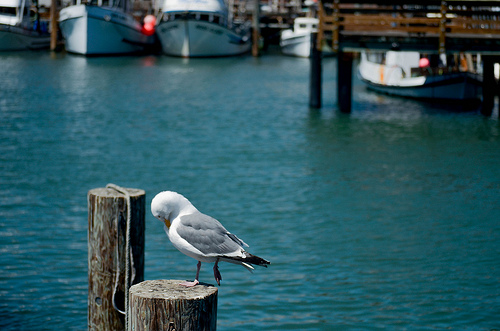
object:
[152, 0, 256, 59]
boat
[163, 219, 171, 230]
beak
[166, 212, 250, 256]
wings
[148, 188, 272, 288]
bird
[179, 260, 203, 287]
foot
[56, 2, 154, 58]
blue boat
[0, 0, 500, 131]
harbor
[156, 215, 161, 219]
eye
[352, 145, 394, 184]
ground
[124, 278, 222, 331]
pole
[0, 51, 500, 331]
river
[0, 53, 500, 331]
water